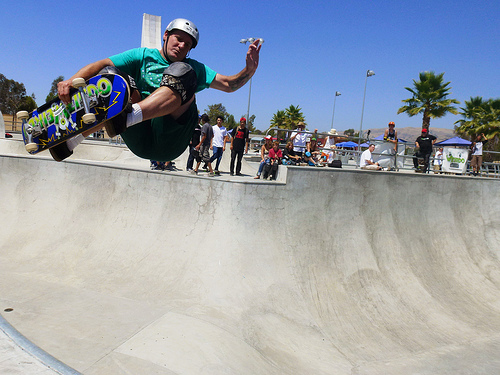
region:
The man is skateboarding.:
[10, 15, 265, 200]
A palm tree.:
[390, 60, 452, 136]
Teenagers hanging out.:
[180, 90, 490, 185]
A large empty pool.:
[1, 140, 491, 365]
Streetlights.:
[320, 55, 385, 135]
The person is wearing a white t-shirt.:
[350, 140, 380, 175]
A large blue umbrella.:
[435, 125, 475, 145]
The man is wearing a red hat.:
[406, 115, 436, 175]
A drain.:
[0, 290, 35, 322]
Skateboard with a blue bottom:
[10, 76, 150, 152]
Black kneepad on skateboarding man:
[152, 56, 204, 105]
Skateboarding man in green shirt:
[3, 0, 277, 171]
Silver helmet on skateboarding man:
[162, 11, 200, 61]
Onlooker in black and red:
[224, 105, 257, 179]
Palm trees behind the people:
[399, 68, 499, 136]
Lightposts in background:
[321, 60, 387, 133]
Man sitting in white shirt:
[348, 140, 384, 172]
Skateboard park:
[17, 181, 463, 323]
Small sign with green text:
[443, 146, 469, 173]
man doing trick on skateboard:
[39, 14, 299, 232]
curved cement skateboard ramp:
[57, 177, 442, 342]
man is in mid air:
[10, 10, 265, 175]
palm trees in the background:
[395, 65, 492, 150]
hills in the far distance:
[255, 106, 470, 146]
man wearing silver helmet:
[160, 10, 210, 55]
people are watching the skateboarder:
[210, 120, 430, 180]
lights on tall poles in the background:
[235, 27, 385, 117]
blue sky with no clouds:
[277, 15, 447, 50]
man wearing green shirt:
[103, 45, 213, 108]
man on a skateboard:
[17, 11, 290, 167]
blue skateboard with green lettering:
[11, 70, 142, 163]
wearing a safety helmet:
[156, 14, 217, 50]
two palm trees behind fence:
[396, 56, 499, 171]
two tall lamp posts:
[321, 54, 383, 154]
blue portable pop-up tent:
[428, 122, 484, 177]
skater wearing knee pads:
[153, 53, 204, 112]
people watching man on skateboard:
[198, 112, 384, 177]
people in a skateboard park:
[13, 18, 480, 336]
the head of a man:
[158, 19, 205, 61]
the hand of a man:
[243, 35, 269, 75]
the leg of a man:
[136, 64, 203, 131]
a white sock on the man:
[121, 99, 144, 126]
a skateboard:
[17, 71, 139, 161]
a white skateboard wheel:
[78, 106, 103, 126]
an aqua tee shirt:
[103, 43, 220, 101]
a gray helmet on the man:
[161, 15, 204, 42]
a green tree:
[397, 60, 459, 122]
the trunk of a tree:
[419, 109, 434, 133]